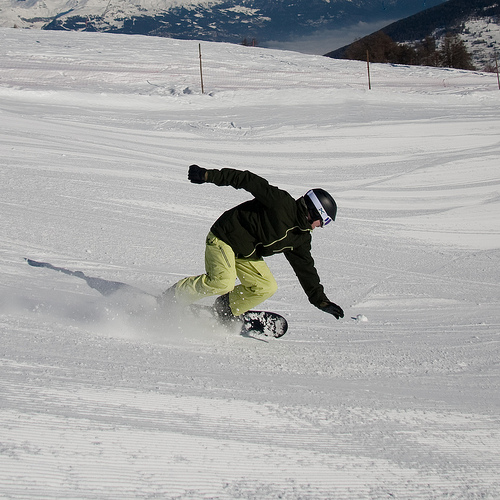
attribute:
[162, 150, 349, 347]
man — snowboarding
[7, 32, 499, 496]
snow — packed down, grooved, flying up, flying, powdered, white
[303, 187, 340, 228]
helmet — black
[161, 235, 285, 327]
pants — yellow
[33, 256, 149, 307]
shadow — gray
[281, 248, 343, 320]
arm — human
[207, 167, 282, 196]
arm — human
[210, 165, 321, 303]
jacket — black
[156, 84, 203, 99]
pile — small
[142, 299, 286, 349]
snowboard — black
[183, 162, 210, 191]
glove — black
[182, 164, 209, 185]
hand — fist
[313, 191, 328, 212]
stripe — gray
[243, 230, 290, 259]
stripe — white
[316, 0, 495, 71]
mountain — snowy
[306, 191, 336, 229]
goggles — white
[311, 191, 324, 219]
band — white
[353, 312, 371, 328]
ball — small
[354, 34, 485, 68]
trees — brown, bare